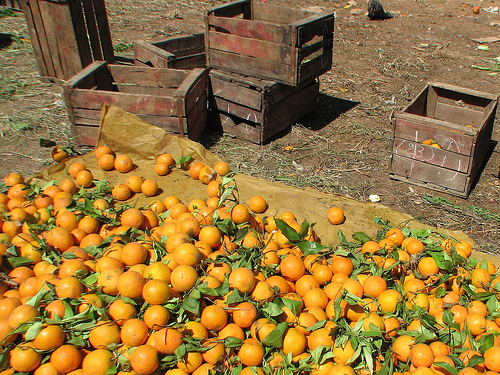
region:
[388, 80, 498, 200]
a brown wooden crate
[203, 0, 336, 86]
a brown wooden crate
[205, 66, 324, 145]
a brown wooden crate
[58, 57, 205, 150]
a brown wooden crate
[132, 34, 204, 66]
a brown wooden crate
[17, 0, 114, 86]
a brown wooden crate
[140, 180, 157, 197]
a ripe orange fruit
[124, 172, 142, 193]
a ripe orange fruit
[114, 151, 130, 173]
a ripe orange fruit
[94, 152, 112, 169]
a ripe orange fruit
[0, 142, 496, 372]
a whole bunch of oranges laying on brown paper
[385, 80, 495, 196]
reddish-brown wood crate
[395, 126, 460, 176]
white writing on side on wooden crate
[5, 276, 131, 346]
green leaves on the end of oranges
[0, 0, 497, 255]
brown dirt that the crates and oranges are laying on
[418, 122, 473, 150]
oranges laying inside the crate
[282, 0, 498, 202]
trash and old fruit laying on the dirt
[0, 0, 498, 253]
dead grass laid over on the dirt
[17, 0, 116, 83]
reddish-brown wooden crate sitting up on its side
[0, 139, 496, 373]
large group of oranges on ground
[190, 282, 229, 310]
green leaf top of oranges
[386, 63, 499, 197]
wooden box with oranges in them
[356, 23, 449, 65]
patch of dirt ground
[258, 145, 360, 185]
green blades of grass on dirt ground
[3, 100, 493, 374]
brown paper bag with oranges on top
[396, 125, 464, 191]
white writing on side of wooden box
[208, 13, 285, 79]
red number sign on side of wooden crate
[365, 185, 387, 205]
piece of white debri on ground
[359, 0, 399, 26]
black object on dirt ground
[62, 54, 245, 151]
wooden crates with markings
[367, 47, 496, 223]
wooden crates with markings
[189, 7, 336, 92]
wooden crates with markings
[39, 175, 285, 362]
oranges on the ground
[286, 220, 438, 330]
oranges on the ground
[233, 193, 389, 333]
oranges on the ground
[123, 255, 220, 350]
oranges on the ground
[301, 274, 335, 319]
oranges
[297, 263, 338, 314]
the oranges are orange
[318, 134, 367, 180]
grass on the ground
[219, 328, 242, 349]
the green leaves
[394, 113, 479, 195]
a box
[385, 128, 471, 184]
white writing on the box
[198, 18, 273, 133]
two boxes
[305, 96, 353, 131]
a shadow on the ground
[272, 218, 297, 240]
a leaf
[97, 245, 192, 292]
a batch of oranges